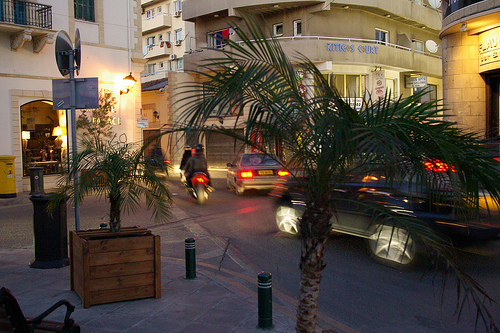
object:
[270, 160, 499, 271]
car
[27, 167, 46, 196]
trash can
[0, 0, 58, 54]
balcony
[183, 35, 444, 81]
balcony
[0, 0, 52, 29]
railing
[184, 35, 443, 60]
railing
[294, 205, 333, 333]
trunk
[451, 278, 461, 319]
leaves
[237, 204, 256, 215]
red reflection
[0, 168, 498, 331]
road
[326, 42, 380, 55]
writing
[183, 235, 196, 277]
pole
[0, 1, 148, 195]
building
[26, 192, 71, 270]
waste bin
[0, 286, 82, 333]
bench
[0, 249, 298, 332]
sidewalk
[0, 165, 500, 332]
floor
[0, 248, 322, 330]
concrete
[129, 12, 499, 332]
tree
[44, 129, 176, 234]
tree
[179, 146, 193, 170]
man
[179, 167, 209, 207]
motorcycle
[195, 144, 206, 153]
helmet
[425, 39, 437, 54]
dish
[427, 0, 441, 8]
dish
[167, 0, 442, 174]
building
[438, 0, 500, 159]
building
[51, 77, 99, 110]
sign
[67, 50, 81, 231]
pole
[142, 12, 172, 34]
balcony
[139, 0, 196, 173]
building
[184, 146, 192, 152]
helmet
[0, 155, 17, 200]
trash can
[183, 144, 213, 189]
man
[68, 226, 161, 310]
crate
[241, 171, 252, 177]
tail lights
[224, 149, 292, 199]
car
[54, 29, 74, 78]
sign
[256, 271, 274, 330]
pole